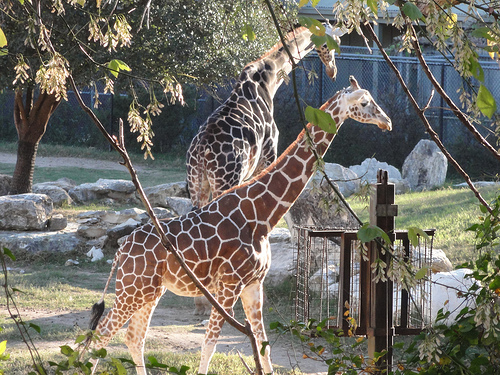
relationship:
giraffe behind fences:
[80, 75, 392, 375] [16, 34, 491, 170]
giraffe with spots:
[96, 90, 433, 368] [204, 205, 243, 239]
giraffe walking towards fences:
[198, 27, 307, 171] [16, 34, 491, 170]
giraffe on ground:
[198, 27, 307, 171] [25, 166, 483, 359]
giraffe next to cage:
[96, 90, 433, 368] [294, 227, 434, 327]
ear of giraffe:
[346, 70, 357, 89] [96, 90, 433, 368]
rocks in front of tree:
[0, 139, 487, 337] [8, 11, 68, 193]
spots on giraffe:
[204, 205, 243, 239] [96, 90, 433, 368]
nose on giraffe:
[376, 112, 401, 141] [96, 90, 433, 368]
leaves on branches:
[342, 14, 369, 43] [376, 17, 499, 108]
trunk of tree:
[4, 93, 46, 176] [8, 11, 68, 193]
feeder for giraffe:
[295, 228, 433, 328] [80, 75, 392, 375]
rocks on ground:
[15, 144, 489, 262] [25, 166, 483, 359]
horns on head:
[345, 70, 370, 85] [325, 81, 390, 134]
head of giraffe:
[325, 81, 390, 134] [80, 75, 392, 375]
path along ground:
[111, 287, 244, 373] [25, 166, 483, 359]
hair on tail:
[92, 302, 101, 332] [81, 239, 131, 331]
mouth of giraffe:
[382, 116, 400, 136] [96, 90, 433, 368]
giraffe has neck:
[96, 90, 433, 368] [254, 0, 291, 94]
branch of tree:
[47, 99, 64, 132] [8, 11, 68, 193]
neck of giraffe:
[254, 0, 291, 94] [96, 90, 433, 368]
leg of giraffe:
[230, 274, 283, 361] [96, 90, 433, 368]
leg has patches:
[230, 274, 283, 361] [236, 288, 262, 309]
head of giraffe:
[325, 81, 390, 134] [96, 90, 433, 368]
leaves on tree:
[342, 14, 369, 43] [346, 6, 499, 186]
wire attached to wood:
[312, 223, 421, 329] [370, 182, 398, 347]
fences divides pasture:
[16, 34, 491, 170] [19, 48, 448, 370]